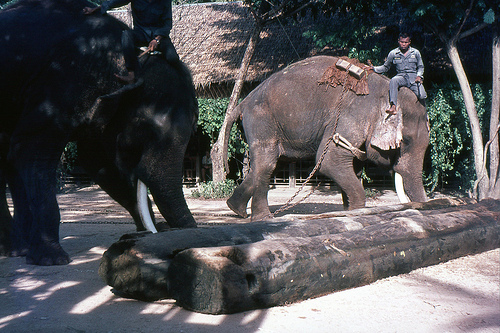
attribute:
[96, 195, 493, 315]
log — huge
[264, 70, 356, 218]
chain — long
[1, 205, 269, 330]
shadow — large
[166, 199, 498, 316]
tree log — huge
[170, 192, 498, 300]
poles — wood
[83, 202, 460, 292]
poles — wood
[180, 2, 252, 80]
straw hut — large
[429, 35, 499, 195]
tree trunk — pictured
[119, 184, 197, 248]
tusk — large, white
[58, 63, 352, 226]
chain — silver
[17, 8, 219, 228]
elephant — dark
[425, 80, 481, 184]
bush — green, leafy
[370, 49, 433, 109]
clothing — blue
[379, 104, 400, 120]
shoes — brown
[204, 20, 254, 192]
tree — dead